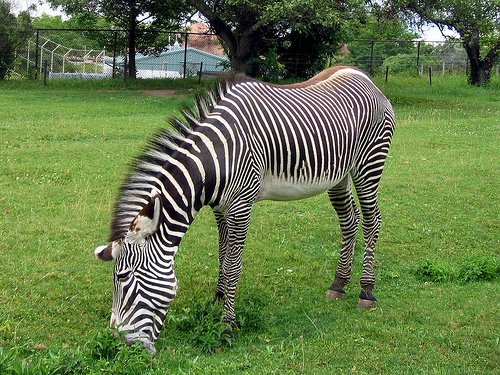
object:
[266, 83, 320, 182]
stripe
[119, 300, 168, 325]
stripe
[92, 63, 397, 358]
zebra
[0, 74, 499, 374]
field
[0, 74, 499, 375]
grass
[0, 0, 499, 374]
outdoors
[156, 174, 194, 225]
black stripe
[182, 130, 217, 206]
black stripe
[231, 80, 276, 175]
black stripe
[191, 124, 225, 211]
black stripe